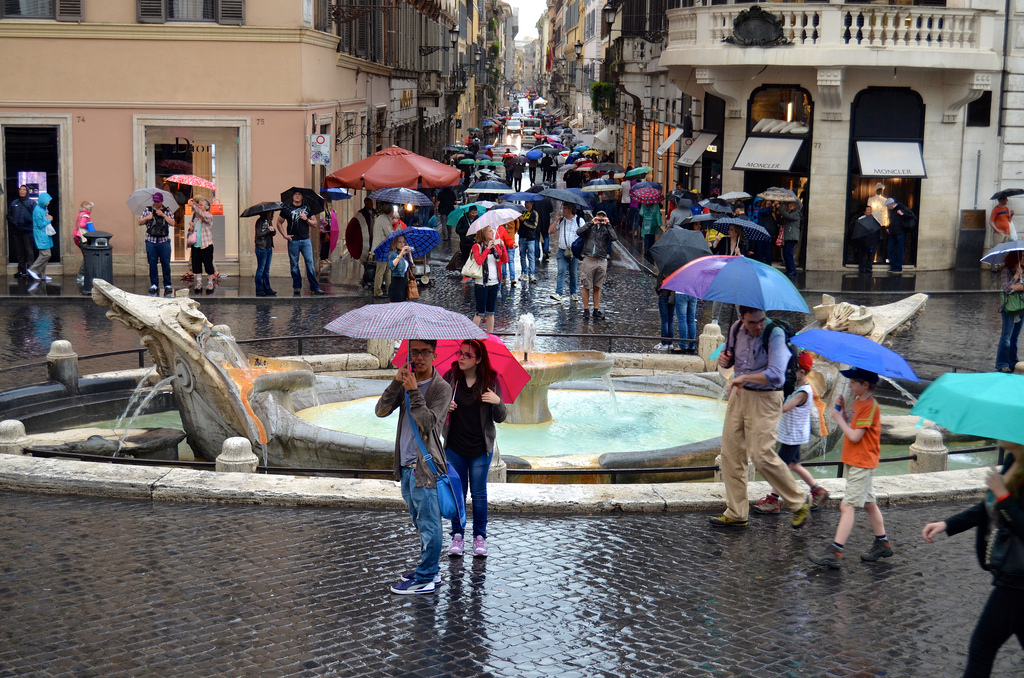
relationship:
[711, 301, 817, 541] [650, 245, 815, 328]
man carrying umbrella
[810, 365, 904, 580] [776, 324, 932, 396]
boy holding umbrella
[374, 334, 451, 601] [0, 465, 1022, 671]
boy on street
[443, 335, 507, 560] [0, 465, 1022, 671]
person on street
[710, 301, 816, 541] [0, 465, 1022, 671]
man on street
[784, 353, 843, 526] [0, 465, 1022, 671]
person on street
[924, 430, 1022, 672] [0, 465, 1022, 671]
person on street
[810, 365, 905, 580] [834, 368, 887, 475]
boy wearing shirt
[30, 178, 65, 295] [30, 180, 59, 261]
person wearing jacket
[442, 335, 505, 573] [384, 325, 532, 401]
person with umbrella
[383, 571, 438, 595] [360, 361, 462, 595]
shoe on boy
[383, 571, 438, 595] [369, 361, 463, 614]
shoe on boy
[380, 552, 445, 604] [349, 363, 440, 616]
shoe on boy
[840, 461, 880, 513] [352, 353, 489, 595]
shorts on boy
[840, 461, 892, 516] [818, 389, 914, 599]
shorts of boy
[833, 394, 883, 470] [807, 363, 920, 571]
shirt on boy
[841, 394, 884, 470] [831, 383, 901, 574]
shirt on boy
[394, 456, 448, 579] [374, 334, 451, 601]
jeans on boy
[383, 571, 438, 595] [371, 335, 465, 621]
shoe on boy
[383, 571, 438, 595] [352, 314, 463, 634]
shoe on boy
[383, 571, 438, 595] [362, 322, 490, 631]
shoe on boy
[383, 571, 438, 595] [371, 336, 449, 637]
shoe on boy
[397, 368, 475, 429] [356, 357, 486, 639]
arm of boy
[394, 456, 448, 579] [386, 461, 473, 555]
jeans on man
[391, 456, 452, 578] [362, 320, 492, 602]
jeans on man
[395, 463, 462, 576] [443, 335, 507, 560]
jeans on person